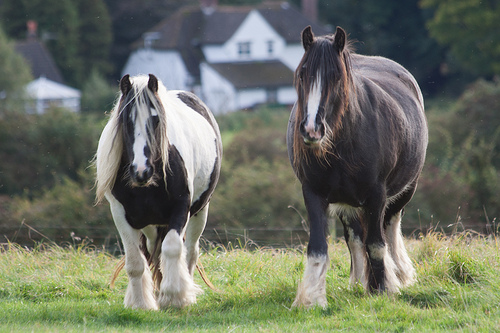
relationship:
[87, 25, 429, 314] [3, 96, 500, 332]
two horses are in a field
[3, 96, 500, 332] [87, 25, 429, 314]
field has horses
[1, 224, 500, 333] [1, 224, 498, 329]
grass has grass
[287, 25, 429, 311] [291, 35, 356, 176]
horse has mane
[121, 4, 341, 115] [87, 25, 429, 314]
house in back of horses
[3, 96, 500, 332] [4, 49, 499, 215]
field has bushes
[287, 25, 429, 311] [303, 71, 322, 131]
horse has white accents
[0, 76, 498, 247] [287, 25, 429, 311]
bushes behind horse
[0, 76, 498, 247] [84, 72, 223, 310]
bushes behind horse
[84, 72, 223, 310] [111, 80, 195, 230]
white horse has brown patches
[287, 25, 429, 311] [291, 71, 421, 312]
horse has white accents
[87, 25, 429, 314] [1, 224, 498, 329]
horses are walking on grass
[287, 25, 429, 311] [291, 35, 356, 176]
horse has long hair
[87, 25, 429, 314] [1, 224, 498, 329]
two horses are walking on grass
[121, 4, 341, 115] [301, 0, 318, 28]
house has fireplace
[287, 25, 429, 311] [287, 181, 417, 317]
horse walking slow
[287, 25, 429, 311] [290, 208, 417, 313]
horse has white fur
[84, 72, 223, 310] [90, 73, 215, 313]
horse has white fur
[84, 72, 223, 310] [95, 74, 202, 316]
horse has white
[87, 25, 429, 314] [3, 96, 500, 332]
two horses standing on top of a field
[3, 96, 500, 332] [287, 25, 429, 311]
field has a horse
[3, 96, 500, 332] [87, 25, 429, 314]
field has two horses